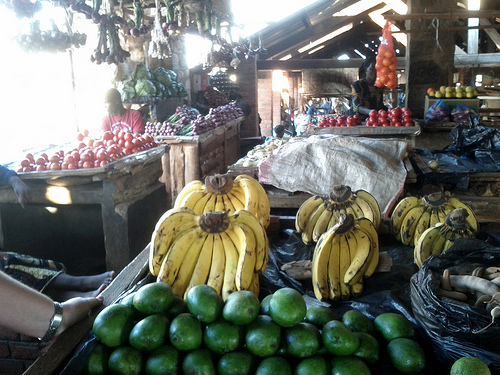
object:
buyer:
[349, 56, 388, 116]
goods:
[316, 104, 414, 128]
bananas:
[413, 210, 479, 265]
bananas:
[388, 185, 478, 245]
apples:
[430, 79, 480, 103]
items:
[430, 262, 497, 332]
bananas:
[147, 201, 272, 299]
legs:
[7, 247, 113, 302]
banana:
[177, 158, 286, 232]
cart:
[37, 180, 499, 373]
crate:
[12, 113, 246, 206]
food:
[5, 0, 241, 161]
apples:
[357, 104, 420, 131]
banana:
[230, 219, 256, 291]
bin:
[12, 165, 167, 188]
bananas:
[310, 197, 372, 297]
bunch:
[145, 202, 271, 292]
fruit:
[43, 169, 491, 374]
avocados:
[86, 280, 428, 374]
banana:
[142, 210, 189, 277]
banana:
[302, 227, 330, 302]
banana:
[205, 232, 227, 296]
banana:
[234, 174, 259, 215]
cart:
[0, 96, 250, 278]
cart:
[223, 136, 413, 212]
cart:
[305, 104, 420, 149]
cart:
[405, 123, 498, 224]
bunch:
[312, 222, 397, 291]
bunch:
[399, 204, 449, 246]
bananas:
[343, 219, 375, 291]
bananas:
[137, 169, 277, 299]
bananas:
[291, 185, 326, 249]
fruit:
[174, 178, 258, 363]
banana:
[189, 193, 267, 287]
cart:
[129, 149, 394, 311]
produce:
[92, 182, 498, 370]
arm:
[0, 271, 53, 341]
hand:
[48, 294, 105, 342]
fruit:
[106, 275, 254, 372]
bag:
[374, 19, 397, 89]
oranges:
[375, 19, 398, 89]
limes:
[111, 283, 341, 373]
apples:
[58, 121, 154, 166]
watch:
[35, 294, 65, 345]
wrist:
[29, 294, 63, 343]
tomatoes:
[16, 125, 144, 172]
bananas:
[294, 186, 381, 238]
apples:
[30, 150, 107, 170]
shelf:
[14, 345, 90, 366]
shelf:
[111, 271, 139, 287]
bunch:
[306, 204, 387, 302]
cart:
[268, 179, 368, 334]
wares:
[13, 119, 484, 372]